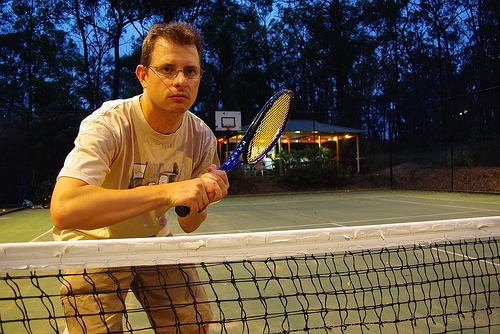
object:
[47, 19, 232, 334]
man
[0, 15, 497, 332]
tennis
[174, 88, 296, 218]
tennis racket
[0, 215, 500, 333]
net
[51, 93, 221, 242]
shirt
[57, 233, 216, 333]
shorts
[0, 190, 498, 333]
court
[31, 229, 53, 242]
paint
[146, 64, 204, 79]
glasses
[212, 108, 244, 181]
basketball goal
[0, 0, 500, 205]
background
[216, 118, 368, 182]
tent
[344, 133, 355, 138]
light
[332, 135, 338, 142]
light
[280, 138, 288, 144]
light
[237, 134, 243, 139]
light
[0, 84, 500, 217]
fence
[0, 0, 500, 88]
sky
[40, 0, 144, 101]
tree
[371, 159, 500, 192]
ground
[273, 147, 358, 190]
bushes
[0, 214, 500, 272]
top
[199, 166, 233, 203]
hand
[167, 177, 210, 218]
hand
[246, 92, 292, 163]
webbing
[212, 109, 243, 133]
backboard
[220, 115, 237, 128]
box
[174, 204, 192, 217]
handle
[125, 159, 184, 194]
design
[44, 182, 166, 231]
forearm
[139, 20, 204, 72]
hair